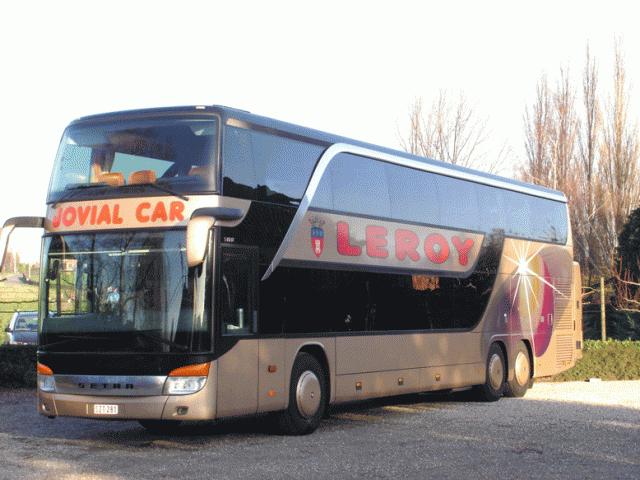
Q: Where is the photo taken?
A: On the street.